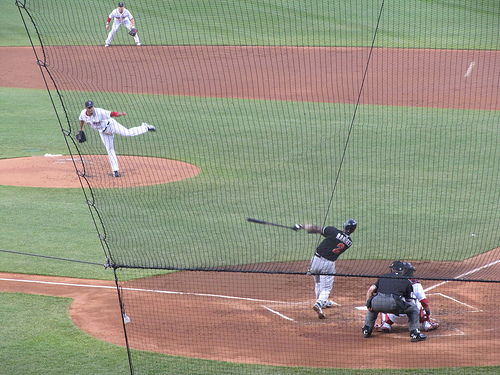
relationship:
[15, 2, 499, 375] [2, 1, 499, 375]
netting on field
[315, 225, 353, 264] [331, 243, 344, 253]
jersey has a 2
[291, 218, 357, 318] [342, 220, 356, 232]
batter wearing a helmet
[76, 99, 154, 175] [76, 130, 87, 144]
baseball player wearing a glove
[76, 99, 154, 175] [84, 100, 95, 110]
baseball player wearing a cap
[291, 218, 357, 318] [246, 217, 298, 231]
batter swinging a bat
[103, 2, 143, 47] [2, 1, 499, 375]
baseball player on field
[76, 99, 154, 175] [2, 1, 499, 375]
baseball player on field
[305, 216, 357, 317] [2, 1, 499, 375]
baseball player on field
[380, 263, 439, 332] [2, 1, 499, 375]
baseball player on field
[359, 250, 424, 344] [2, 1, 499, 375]
catcher on field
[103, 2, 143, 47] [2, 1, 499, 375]
baseball player standing on field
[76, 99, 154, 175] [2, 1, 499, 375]
baseball player standing on field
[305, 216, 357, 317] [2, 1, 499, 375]
baseball player standing on field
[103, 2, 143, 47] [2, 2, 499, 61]
baseball player in outfield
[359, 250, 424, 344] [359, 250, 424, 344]
catcher next catcher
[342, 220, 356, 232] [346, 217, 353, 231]
helmet has back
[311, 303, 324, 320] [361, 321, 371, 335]
shoe has back